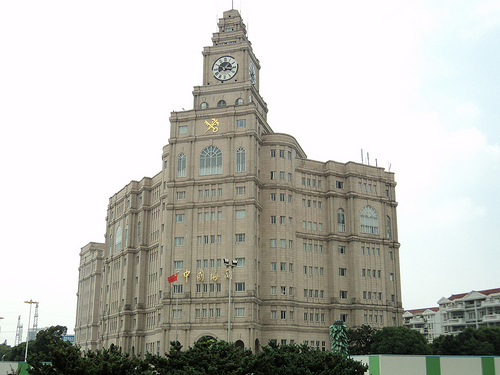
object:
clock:
[211, 56, 237, 82]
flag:
[164, 274, 180, 283]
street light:
[223, 259, 226, 266]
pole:
[229, 264, 231, 375]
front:
[162, 11, 256, 359]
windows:
[195, 145, 222, 176]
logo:
[202, 118, 221, 134]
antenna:
[231, 0, 233, 11]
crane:
[23, 300, 41, 340]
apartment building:
[401, 287, 499, 345]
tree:
[330, 322, 354, 357]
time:
[224, 60, 237, 70]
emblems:
[182, 269, 230, 283]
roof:
[404, 308, 439, 313]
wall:
[2, 356, 499, 375]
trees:
[429, 328, 498, 357]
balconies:
[446, 309, 466, 325]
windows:
[197, 209, 222, 222]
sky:
[0, 0, 500, 347]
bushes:
[247, 339, 369, 375]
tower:
[13, 315, 22, 349]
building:
[60, 3, 406, 363]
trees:
[147, 334, 264, 375]